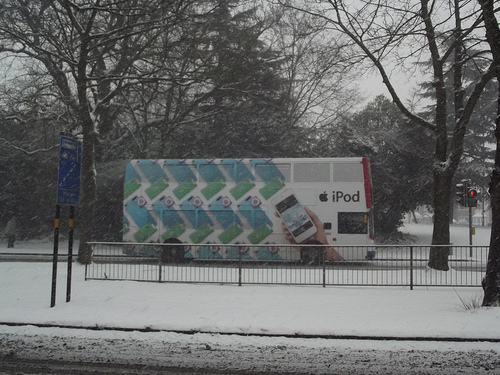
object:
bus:
[117, 152, 396, 269]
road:
[41, 251, 439, 273]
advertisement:
[268, 182, 370, 205]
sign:
[52, 130, 83, 208]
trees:
[32, 50, 156, 264]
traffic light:
[452, 181, 488, 259]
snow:
[200, 286, 457, 326]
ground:
[34, 275, 489, 331]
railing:
[96, 241, 374, 253]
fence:
[76, 240, 489, 290]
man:
[4, 211, 19, 251]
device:
[5, 224, 8, 233]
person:
[6, 202, 27, 256]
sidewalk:
[99, 255, 445, 281]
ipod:
[327, 189, 371, 202]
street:
[401, 255, 497, 271]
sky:
[267, 30, 434, 95]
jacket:
[7, 216, 15, 233]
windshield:
[367, 215, 376, 235]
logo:
[317, 191, 329, 202]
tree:
[394, 54, 484, 269]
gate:
[183, 209, 295, 258]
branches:
[363, 35, 475, 123]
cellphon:
[271, 186, 323, 246]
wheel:
[160, 238, 186, 263]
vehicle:
[122, 180, 380, 255]